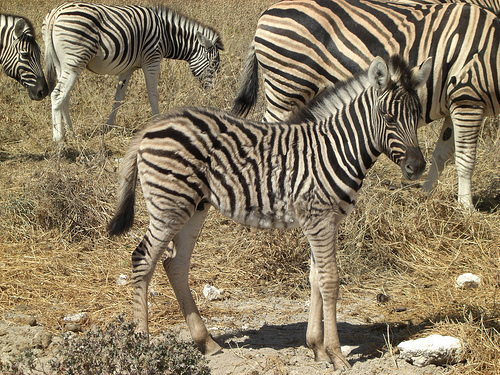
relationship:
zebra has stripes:
[104, 56, 432, 371] [329, 118, 362, 175]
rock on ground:
[403, 332, 458, 365] [234, 305, 276, 352]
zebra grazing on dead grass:
[45, 6, 227, 108] [77, 125, 113, 165]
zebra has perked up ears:
[104, 56, 432, 371] [371, 58, 434, 88]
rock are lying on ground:
[395, 332, 465, 367] [229, 278, 287, 357]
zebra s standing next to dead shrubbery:
[104, 56, 432, 371] [24, 315, 196, 369]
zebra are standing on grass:
[104, 56, 432, 371] [34, 242, 103, 305]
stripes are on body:
[331, 109, 368, 159] [208, 130, 319, 208]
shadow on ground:
[249, 313, 306, 359] [207, 258, 292, 329]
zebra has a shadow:
[104, 56, 432, 371] [247, 318, 293, 350]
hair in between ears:
[394, 55, 414, 89] [365, 52, 395, 91]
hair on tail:
[104, 210, 133, 237] [113, 142, 138, 238]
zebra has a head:
[104, 56, 432, 371] [363, 51, 433, 180]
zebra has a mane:
[104, 56, 432, 371] [312, 88, 359, 110]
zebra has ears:
[104, 56, 432, 371] [367, 54, 429, 90]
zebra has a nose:
[104, 56, 432, 371] [405, 150, 424, 176]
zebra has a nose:
[104, 56, 432, 371] [405, 165, 415, 174]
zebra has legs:
[104, 56, 432, 371] [298, 210, 350, 367]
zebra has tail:
[104, 56, 432, 371] [104, 136, 144, 241]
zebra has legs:
[104, 56, 432, 371] [129, 202, 228, 360]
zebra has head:
[104, 51, 444, 365] [363, 49, 426, 183]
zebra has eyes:
[104, 51, 444, 365] [377, 104, 421, 123]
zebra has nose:
[104, 51, 444, 365] [403, 154, 431, 179]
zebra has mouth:
[104, 56, 432, 371] [394, 147, 428, 184]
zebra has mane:
[104, 51, 444, 365] [291, 45, 413, 132]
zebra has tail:
[104, 56, 432, 371] [102, 130, 145, 242]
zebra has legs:
[104, 56, 432, 371] [297, 214, 363, 373]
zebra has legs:
[104, 56, 432, 371] [123, 191, 227, 358]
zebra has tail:
[104, 56, 432, 371] [104, 129, 140, 239]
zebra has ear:
[104, 56, 432, 371] [365, 45, 435, 88]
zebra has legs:
[104, 56, 432, 371] [298, 202, 355, 372]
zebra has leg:
[104, 56, 432, 371] [122, 188, 189, 341]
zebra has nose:
[104, 56, 432, 371] [402, 142, 428, 180]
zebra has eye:
[104, 51, 444, 365] [384, 108, 399, 130]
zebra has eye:
[104, 56, 432, 371] [382, 108, 399, 126]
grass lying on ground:
[213, 163, 497, 303] [2, 5, 497, 370]